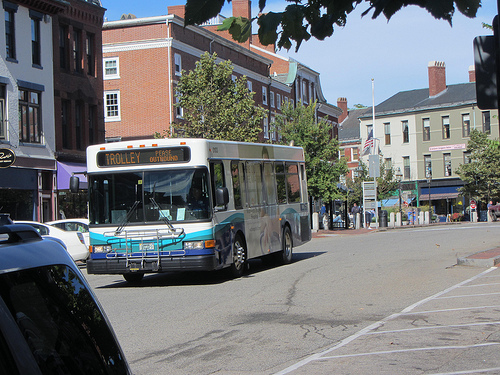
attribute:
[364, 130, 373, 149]
flag — american, half mast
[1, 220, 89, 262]
car — white, parked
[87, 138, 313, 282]
bus — blue, white, on duty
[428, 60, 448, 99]
chimney — brick, red, large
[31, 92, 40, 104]
window — exterior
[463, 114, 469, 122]
curtain — white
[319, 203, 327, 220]
person — wearing blue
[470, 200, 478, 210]
sign — red, white, do not enter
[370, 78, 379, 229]
pole — white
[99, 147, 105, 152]
light — orange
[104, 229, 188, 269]
rack — metal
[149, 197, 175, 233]
wiper — black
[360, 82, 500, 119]
roof — grey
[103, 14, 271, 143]
building — brick, red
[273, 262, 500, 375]
line — no parking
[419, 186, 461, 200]
awning — blue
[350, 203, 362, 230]
person — walking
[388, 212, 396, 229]
barricade — concrete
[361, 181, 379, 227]
sign — for bus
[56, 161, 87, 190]
awning — purple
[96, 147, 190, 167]
display — led